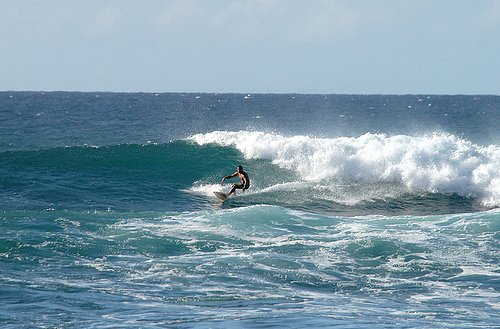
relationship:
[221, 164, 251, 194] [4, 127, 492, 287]
person riding wave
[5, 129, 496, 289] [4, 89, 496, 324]
waves of ocean